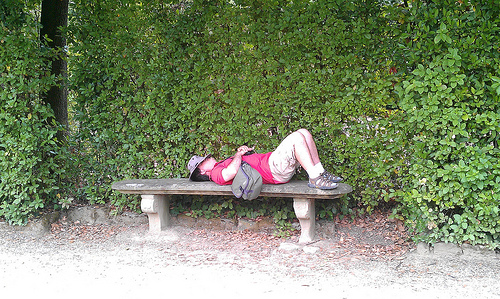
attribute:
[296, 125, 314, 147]
knee — raised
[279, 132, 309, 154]
knee — raised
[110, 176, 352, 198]
concrete slab — dark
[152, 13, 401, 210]
bushes — green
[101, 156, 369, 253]
bench — cement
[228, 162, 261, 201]
satchel — tan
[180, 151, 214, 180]
hat — brown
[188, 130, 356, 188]
man — lying down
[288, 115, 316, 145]
knees — white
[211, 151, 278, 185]
shirt — red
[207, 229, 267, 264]
leaves — brown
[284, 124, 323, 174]
legs — bare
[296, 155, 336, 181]
socks — white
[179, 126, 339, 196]
man — sleeping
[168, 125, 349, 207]
person — laying outside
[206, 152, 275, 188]
t-shirt — red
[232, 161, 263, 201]
bag — purple and sage green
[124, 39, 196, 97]
foliage — green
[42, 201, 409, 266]
leaves — brown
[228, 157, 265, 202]
pack — gray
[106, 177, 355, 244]
bench — concrete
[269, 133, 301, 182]
shorts — tan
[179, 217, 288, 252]
leaves — dead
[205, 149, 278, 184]
shirt — red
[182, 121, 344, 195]
man — laying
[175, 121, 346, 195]
person — lying down